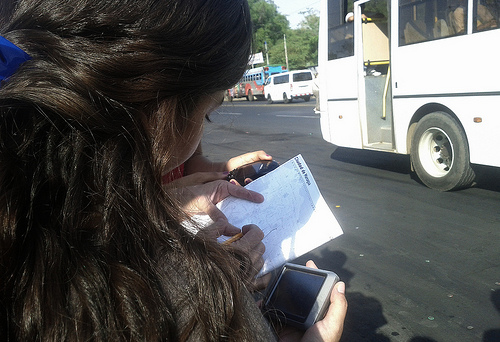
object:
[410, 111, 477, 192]
tire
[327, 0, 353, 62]
window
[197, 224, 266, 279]
hand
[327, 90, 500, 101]
stripe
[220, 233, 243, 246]
pencil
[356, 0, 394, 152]
door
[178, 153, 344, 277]
paper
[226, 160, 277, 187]
phone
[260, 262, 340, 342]
device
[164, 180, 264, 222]
hand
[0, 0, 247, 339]
hair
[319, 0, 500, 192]
bus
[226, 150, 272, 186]
left hand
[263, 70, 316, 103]
van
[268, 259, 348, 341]
hand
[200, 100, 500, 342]
pavement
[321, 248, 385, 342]
shadow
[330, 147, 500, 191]
shadow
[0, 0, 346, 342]
woman